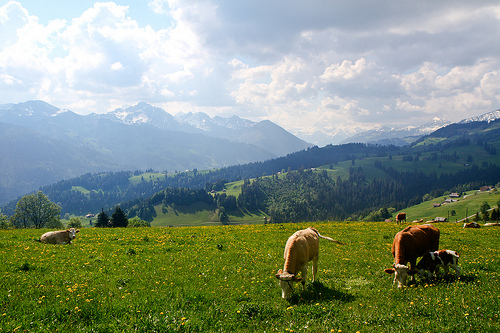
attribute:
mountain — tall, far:
[80, 62, 241, 156]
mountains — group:
[0, 90, 274, 122]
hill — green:
[64, 134, 206, 250]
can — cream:
[455, 205, 493, 240]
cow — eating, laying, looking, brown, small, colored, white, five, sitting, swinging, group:
[272, 212, 345, 330]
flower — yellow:
[58, 236, 108, 319]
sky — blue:
[126, 17, 153, 43]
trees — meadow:
[194, 169, 287, 209]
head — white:
[272, 272, 303, 302]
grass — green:
[145, 228, 199, 325]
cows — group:
[263, 183, 457, 301]